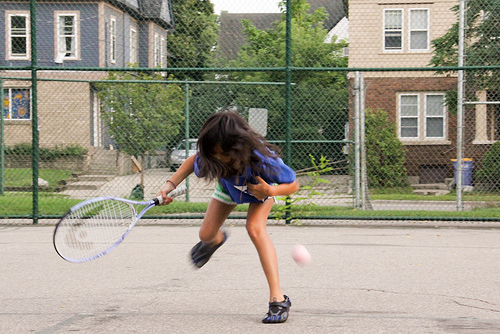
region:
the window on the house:
[396, 89, 451, 148]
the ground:
[403, 248, 465, 303]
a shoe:
[261, 305, 289, 321]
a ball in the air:
[287, 242, 314, 267]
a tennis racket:
[54, 193, 161, 266]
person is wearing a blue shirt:
[257, 158, 285, 173]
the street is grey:
[363, 234, 463, 304]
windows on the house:
[55, 15, 82, 58]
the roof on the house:
[217, 20, 247, 60]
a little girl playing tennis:
[47, 103, 316, 326]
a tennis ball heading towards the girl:
[287, 242, 310, 264]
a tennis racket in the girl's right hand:
[46, 180, 188, 264]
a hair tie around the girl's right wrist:
[165, 175, 177, 190]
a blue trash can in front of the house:
[450, 155, 473, 189]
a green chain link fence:
[0, 0, 499, 224]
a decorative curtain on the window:
[1, 85, 32, 120]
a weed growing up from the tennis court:
[265, 152, 335, 220]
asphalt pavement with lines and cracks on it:
[0, 217, 498, 332]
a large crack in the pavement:
[331, 282, 498, 317]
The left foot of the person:
[260, 293, 296, 325]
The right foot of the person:
[189, 230, 225, 270]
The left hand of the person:
[243, 173, 274, 203]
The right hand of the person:
[151, 181, 179, 207]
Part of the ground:
[385, 271, 440, 306]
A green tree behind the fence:
[86, 60, 186, 175]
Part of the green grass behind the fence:
[325, 205, 345, 211]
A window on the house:
[47, 7, 82, 62]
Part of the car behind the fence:
[171, 150, 177, 160]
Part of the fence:
[273, 88, 298, 119]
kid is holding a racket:
[55, 98, 298, 305]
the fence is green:
[251, 40, 446, 216]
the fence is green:
[306, 101, 455, 228]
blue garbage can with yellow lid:
[451, 155, 472, 182]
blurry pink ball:
[293, 243, 309, 263]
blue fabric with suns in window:
[3, 88, 28, 116]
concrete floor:
[1, 218, 496, 329]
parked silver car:
[169, 135, 198, 170]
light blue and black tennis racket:
[52, 187, 184, 264]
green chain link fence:
[0, 0, 499, 224]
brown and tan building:
[345, 3, 497, 177]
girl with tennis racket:
[156, 109, 302, 322]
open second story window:
[381, 8, 403, 52]